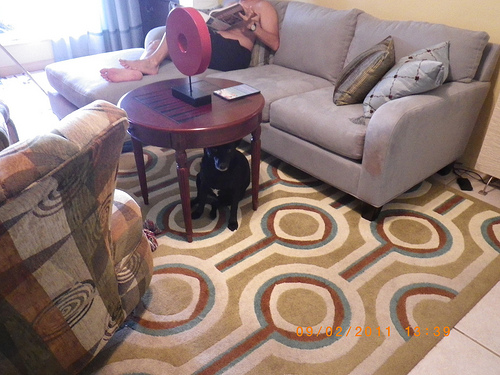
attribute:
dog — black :
[194, 144, 257, 223]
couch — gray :
[36, 1, 498, 229]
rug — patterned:
[85, 135, 498, 375]